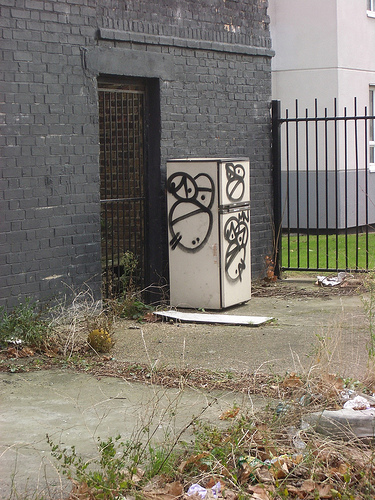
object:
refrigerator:
[164, 152, 254, 312]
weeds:
[116, 250, 147, 299]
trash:
[311, 383, 374, 442]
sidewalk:
[3, 273, 374, 498]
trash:
[310, 270, 354, 291]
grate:
[97, 82, 157, 310]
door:
[100, 73, 152, 305]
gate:
[268, 91, 374, 278]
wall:
[2, 2, 276, 339]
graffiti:
[167, 169, 217, 254]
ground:
[1, 231, 375, 498]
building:
[0, 2, 287, 349]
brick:
[27, 81, 49, 97]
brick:
[51, 164, 62, 173]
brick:
[42, 20, 72, 36]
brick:
[11, 17, 28, 32]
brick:
[0, 166, 21, 181]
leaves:
[236, 455, 253, 484]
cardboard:
[151, 305, 280, 327]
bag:
[302, 385, 375, 440]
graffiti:
[225, 214, 253, 285]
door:
[219, 203, 255, 313]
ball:
[84, 318, 119, 354]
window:
[367, 142, 374, 167]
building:
[269, 1, 375, 240]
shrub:
[1, 298, 48, 356]